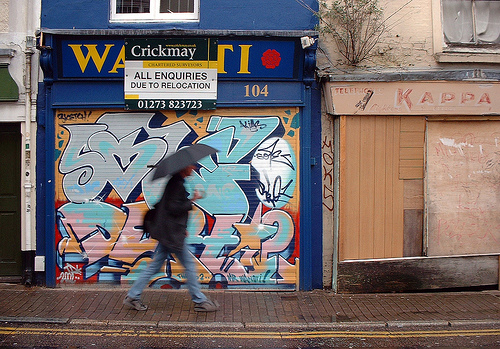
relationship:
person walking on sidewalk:
[126, 139, 223, 316] [8, 281, 499, 348]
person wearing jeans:
[126, 139, 223, 316] [129, 240, 206, 301]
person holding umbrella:
[126, 139, 223, 316] [156, 140, 222, 198]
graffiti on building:
[57, 105, 299, 290] [34, 8, 323, 290]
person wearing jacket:
[126, 139, 223, 316] [149, 180, 190, 253]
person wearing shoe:
[126, 139, 223, 316] [194, 297, 221, 311]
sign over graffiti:
[124, 38, 222, 110] [57, 105, 299, 290]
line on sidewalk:
[5, 323, 500, 339] [8, 281, 499, 348]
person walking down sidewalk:
[126, 139, 223, 316] [8, 281, 499, 348]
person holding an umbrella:
[126, 139, 223, 316] [156, 140, 222, 198]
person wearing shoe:
[126, 139, 223, 316] [123, 291, 150, 311]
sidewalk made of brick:
[8, 281, 499, 348] [344, 300, 363, 312]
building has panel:
[317, 3, 500, 292] [439, 5, 480, 47]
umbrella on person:
[156, 140, 222, 198] [126, 139, 223, 316]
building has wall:
[317, 3, 500, 292] [323, 73, 500, 289]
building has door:
[317, 3, 500, 292] [430, 120, 499, 258]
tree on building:
[318, 7, 422, 72] [317, 3, 500, 292]